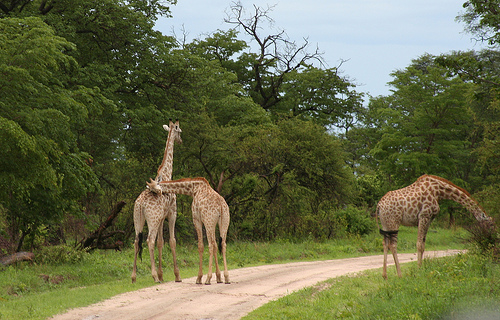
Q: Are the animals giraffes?
A: Yes, all the animals are giraffes.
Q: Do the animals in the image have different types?
A: No, all the animals are giraffes.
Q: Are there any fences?
A: No, there are no fences.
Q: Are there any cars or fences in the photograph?
A: No, there are no fences or cars.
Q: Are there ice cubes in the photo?
A: No, there are no ice cubes.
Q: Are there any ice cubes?
A: No, there are no ice cubes.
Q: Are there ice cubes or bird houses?
A: No, there are no ice cubes or bird houses.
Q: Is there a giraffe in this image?
A: Yes, there is a giraffe.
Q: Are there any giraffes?
A: Yes, there is a giraffe.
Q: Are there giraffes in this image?
A: Yes, there is a giraffe.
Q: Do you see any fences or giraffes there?
A: Yes, there is a giraffe.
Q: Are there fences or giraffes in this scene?
A: Yes, there is a giraffe.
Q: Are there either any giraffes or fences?
A: Yes, there is a giraffe.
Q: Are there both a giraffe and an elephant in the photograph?
A: No, there is a giraffe but no elephants.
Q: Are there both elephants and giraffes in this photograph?
A: No, there is a giraffe but no elephants.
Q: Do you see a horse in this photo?
A: No, there are no horses.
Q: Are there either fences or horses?
A: No, there are no horses or fences.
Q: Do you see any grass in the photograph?
A: Yes, there is grass.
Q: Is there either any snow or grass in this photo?
A: Yes, there is grass.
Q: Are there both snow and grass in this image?
A: No, there is grass but no snow.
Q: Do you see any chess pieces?
A: No, there are no chess pieces.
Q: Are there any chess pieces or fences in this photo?
A: No, there are no chess pieces or fences.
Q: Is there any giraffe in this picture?
A: Yes, there is a giraffe.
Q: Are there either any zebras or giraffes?
A: Yes, there is a giraffe.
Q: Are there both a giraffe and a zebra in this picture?
A: No, there is a giraffe but no zebras.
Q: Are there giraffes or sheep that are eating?
A: Yes, the giraffe is eating.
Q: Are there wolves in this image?
A: No, there are no wolves.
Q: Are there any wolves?
A: No, there are no wolves.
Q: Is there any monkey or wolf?
A: No, there are no wolves or monkeys.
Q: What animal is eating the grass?
A: The giraffe is eating the grass.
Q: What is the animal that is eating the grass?
A: The animal is a giraffe.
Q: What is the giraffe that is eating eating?
A: The giraffe is eating grass.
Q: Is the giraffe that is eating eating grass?
A: Yes, the giraffe is eating grass.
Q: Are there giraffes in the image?
A: Yes, there is a giraffe.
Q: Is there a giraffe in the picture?
A: Yes, there is a giraffe.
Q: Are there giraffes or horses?
A: Yes, there is a giraffe.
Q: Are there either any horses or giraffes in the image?
A: Yes, there is a giraffe.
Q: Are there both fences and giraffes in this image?
A: No, there is a giraffe but no fences.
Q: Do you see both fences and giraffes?
A: No, there is a giraffe but no fences.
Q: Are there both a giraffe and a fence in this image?
A: No, there is a giraffe but no fences.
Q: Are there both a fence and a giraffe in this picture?
A: No, there is a giraffe but no fences.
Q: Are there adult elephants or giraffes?
A: Yes, there is an adult giraffe.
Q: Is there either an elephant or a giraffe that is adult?
A: Yes, the giraffe is adult.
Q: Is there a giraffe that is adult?
A: Yes, there is an adult giraffe.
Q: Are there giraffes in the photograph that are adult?
A: Yes, there is an adult giraffe.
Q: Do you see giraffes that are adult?
A: Yes, there is a giraffe that is adult.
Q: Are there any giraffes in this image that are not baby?
A: Yes, there is a adult giraffe.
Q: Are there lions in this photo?
A: No, there are no lions.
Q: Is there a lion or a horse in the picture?
A: No, there are no lions or horses.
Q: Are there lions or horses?
A: No, there are no lions or horses.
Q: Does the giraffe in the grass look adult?
A: Yes, the giraffe is adult.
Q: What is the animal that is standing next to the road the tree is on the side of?
A: The animal is a giraffe.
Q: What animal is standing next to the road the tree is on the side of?
A: The animal is a giraffe.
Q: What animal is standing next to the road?
A: The animal is a giraffe.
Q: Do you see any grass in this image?
A: Yes, there is grass.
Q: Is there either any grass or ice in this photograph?
A: Yes, there is grass.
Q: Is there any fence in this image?
A: No, there are no fences.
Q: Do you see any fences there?
A: No, there are no fences.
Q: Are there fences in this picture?
A: No, there are no fences.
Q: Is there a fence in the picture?
A: No, there are no fences.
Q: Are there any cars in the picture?
A: No, there are no cars.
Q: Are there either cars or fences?
A: No, there are no cars or fences.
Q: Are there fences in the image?
A: No, there are no fences.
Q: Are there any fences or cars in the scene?
A: No, there are no fences or cars.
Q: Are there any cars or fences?
A: No, there are no fences or cars.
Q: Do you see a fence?
A: No, there are no fences.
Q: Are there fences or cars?
A: No, there are no fences or cars.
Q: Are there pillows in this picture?
A: No, there are no pillows.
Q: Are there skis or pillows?
A: No, there are no pillows or skis.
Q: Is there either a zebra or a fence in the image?
A: No, there are no fences or zebras.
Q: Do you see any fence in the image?
A: No, there are no fences.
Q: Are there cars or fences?
A: No, there are no fences or cars.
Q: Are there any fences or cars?
A: No, there are no fences or cars.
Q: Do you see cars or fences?
A: No, there are no fences or cars.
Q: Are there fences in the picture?
A: No, there are no fences.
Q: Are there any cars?
A: No, there are no cars.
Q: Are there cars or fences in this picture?
A: No, there are no cars or fences.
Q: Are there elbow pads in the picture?
A: No, there are no elbow pads.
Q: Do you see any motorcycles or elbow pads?
A: No, there are no elbow pads or motorcycles.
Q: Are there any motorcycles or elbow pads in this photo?
A: No, there are no elbow pads or motorcycles.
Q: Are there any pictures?
A: No, there are no pictures.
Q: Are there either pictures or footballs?
A: No, there are no pictures or footballs.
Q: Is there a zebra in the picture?
A: No, there are no zebras.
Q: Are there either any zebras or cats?
A: No, there are no zebras or cats.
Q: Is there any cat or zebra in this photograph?
A: No, there are no zebras or cats.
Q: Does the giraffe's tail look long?
A: Yes, the tail is long.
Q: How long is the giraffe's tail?
A: The tail is long.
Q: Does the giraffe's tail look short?
A: No, the tail is long.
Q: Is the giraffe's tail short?
A: No, the tail is long.